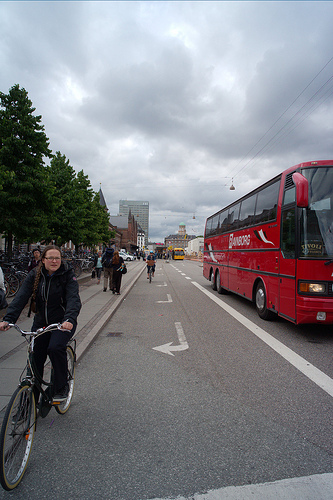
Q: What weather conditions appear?
A: It is cloudy.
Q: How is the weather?
A: It is cloudy.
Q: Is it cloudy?
A: Yes, it is cloudy.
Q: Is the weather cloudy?
A: Yes, it is cloudy.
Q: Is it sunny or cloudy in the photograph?
A: It is cloudy.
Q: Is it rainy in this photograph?
A: No, it is cloudy.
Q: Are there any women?
A: Yes, there is a woman.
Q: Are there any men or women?
A: Yes, there is a woman.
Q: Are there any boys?
A: No, there are no boys.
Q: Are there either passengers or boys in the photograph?
A: No, there are no boys or passengers.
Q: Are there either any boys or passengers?
A: No, there are no boys or passengers.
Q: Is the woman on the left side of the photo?
A: Yes, the woman is on the left of the image.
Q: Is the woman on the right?
A: No, the woman is on the left of the image.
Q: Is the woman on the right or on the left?
A: The woman is on the left of the image.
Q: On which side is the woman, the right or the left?
A: The woman is on the left of the image.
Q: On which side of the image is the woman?
A: The woman is on the left of the image.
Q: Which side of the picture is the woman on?
A: The woman is on the left of the image.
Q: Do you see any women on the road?
A: Yes, there is a woman on the road.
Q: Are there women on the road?
A: Yes, there is a woman on the road.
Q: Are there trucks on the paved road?
A: No, there is a woman on the road.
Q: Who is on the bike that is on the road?
A: The woman is on the bike.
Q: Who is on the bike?
A: The woman is on the bike.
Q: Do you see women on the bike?
A: Yes, there is a woman on the bike.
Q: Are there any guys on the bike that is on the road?
A: No, there is a woman on the bike.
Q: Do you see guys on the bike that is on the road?
A: No, there is a woman on the bike.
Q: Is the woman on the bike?
A: Yes, the woman is on the bike.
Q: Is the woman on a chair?
A: No, the woman is on the bike.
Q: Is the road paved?
A: Yes, the road is paved.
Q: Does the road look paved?
A: Yes, the road is paved.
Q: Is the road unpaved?
A: No, the road is paved.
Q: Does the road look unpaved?
A: No, the road is paved.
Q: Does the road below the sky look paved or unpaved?
A: The road is paved.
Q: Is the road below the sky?
A: Yes, the road is below the sky.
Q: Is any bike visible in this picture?
A: Yes, there is a bike.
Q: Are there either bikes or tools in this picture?
A: Yes, there is a bike.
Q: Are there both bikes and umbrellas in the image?
A: No, there is a bike but no umbrellas.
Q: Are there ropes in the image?
A: No, there are no ropes.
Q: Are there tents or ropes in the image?
A: No, there are no ropes or tents.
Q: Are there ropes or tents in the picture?
A: No, there are no ropes or tents.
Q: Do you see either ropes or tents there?
A: No, there are no ropes or tents.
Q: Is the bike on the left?
A: Yes, the bike is on the left of the image.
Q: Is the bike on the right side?
A: No, the bike is on the left of the image.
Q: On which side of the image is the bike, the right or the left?
A: The bike is on the left of the image.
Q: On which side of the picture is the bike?
A: The bike is on the left of the image.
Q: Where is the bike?
A: The bike is on the road.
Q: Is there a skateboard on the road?
A: No, there is a bike on the road.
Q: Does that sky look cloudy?
A: Yes, the sky is cloudy.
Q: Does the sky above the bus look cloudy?
A: Yes, the sky is cloudy.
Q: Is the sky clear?
A: No, the sky is cloudy.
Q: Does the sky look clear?
A: No, the sky is cloudy.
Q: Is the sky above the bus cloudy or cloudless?
A: The sky is cloudy.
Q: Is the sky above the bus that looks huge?
A: Yes, the sky is above the bus.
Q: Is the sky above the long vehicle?
A: Yes, the sky is above the bus.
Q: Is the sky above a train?
A: No, the sky is above the bus.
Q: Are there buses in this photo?
A: Yes, there is a bus.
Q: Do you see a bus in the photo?
A: Yes, there is a bus.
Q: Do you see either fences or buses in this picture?
A: Yes, there is a bus.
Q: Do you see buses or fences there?
A: Yes, there is a bus.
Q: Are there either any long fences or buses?
A: Yes, there is a long bus.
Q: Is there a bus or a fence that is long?
A: Yes, the bus is long.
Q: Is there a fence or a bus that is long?
A: Yes, the bus is long.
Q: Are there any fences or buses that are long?
A: Yes, the bus is long.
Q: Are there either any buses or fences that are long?
A: Yes, the bus is long.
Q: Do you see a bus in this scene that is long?
A: Yes, there is a long bus.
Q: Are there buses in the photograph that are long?
A: Yes, there is a bus that is long.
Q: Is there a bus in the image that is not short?
A: Yes, there is a long bus.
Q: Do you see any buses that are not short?
A: Yes, there is a long bus.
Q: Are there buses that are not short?
A: Yes, there is a long bus.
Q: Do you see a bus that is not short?
A: Yes, there is a long bus.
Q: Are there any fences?
A: No, there are no fences.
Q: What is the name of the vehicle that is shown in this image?
A: The vehicle is a bus.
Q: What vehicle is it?
A: The vehicle is a bus.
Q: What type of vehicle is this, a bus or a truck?
A: This is a bus.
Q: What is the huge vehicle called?
A: The vehicle is a bus.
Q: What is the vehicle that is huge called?
A: The vehicle is a bus.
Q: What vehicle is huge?
A: The vehicle is a bus.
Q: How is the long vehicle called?
A: The vehicle is a bus.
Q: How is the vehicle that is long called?
A: The vehicle is a bus.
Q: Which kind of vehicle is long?
A: The vehicle is a bus.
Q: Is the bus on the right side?
A: Yes, the bus is on the right of the image.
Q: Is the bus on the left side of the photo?
A: No, the bus is on the right of the image.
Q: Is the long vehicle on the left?
A: No, the bus is on the right of the image.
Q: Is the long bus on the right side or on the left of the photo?
A: The bus is on the right of the image.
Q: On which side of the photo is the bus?
A: The bus is on the right of the image.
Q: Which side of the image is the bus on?
A: The bus is on the right of the image.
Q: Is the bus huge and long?
A: Yes, the bus is huge and long.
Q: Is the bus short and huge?
A: No, the bus is huge but long.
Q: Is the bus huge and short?
A: No, the bus is huge but long.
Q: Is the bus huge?
A: Yes, the bus is huge.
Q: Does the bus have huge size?
A: Yes, the bus is huge.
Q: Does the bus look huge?
A: Yes, the bus is huge.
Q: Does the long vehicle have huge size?
A: Yes, the bus is huge.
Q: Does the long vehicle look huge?
A: Yes, the bus is huge.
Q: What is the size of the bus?
A: The bus is huge.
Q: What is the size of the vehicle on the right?
A: The bus is huge.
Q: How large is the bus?
A: The bus is huge.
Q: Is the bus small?
A: No, the bus is huge.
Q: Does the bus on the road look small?
A: No, the bus is huge.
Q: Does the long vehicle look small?
A: No, the bus is huge.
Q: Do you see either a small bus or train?
A: No, there is a bus but it is huge.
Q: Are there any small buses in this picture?
A: No, there is a bus but it is huge.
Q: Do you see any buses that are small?
A: No, there is a bus but it is huge.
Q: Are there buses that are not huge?
A: No, there is a bus but it is huge.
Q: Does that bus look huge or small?
A: The bus is huge.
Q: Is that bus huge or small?
A: The bus is huge.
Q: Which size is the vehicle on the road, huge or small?
A: The bus is huge.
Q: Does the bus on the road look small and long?
A: No, the bus is long but huge.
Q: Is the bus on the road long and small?
A: No, the bus is long but huge.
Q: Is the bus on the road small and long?
A: No, the bus is long but huge.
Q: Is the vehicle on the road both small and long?
A: No, the bus is long but huge.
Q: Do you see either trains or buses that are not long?
A: No, there is a bus but it is long.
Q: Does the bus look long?
A: Yes, the bus is long.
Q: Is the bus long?
A: Yes, the bus is long.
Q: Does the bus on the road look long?
A: Yes, the bus is long.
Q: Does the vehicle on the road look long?
A: Yes, the bus is long.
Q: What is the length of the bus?
A: The bus is long.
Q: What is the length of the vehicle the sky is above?
A: The bus is long.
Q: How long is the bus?
A: The bus is long.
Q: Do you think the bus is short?
A: No, the bus is long.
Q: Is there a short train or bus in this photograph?
A: No, there is a bus but it is long.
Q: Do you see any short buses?
A: No, there is a bus but it is long.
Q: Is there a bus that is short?
A: No, there is a bus but it is long.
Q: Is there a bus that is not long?
A: No, there is a bus but it is long.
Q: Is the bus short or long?
A: The bus is long.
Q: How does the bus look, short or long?
A: The bus is long.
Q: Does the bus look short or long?
A: The bus is long.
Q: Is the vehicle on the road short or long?
A: The bus is long.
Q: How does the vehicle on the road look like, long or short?
A: The bus is long.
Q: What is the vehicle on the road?
A: The vehicle is a bus.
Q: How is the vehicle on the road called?
A: The vehicle is a bus.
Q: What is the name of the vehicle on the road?
A: The vehicle is a bus.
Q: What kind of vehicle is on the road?
A: The vehicle is a bus.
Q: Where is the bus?
A: The bus is on the road.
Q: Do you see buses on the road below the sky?
A: Yes, there is a bus on the road.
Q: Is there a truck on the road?
A: No, there is a bus on the road.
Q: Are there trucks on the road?
A: No, there is a bus on the road.